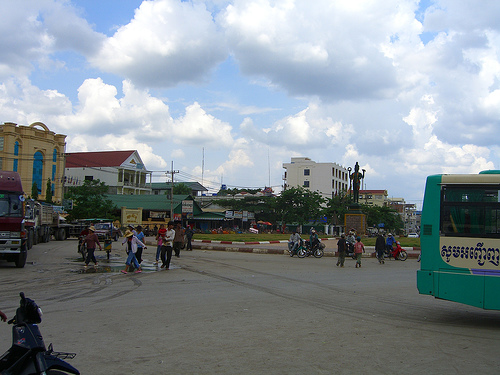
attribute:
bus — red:
[0, 170, 29, 260]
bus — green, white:
[407, 164, 500, 317]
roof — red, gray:
[66, 147, 149, 168]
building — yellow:
[3, 118, 69, 203]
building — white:
[278, 152, 352, 195]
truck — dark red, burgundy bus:
[2, 170, 34, 267]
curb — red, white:
[194, 244, 289, 253]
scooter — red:
[391, 243, 405, 258]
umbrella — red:
[254, 216, 276, 229]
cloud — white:
[4, 4, 498, 141]